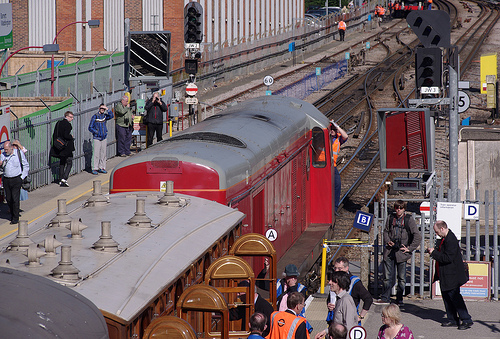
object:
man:
[88, 103, 114, 175]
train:
[0, 95, 334, 339]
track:
[311, 0, 500, 265]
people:
[0, 140, 30, 225]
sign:
[440, 90, 470, 113]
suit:
[51, 118, 76, 182]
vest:
[264, 309, 308, 339]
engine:
[109, 95, 332, 278]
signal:
[414, 47, 443, 173]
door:
[309, 115, 335, 227]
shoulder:
[92, 112, 101, 119]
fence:
[0, 84, 158, 203]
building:
[5, 0, 304, 77]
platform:
[0, 18, 410, 259]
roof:
[109, 95, 330, 192]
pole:
[448, 65, 459, 203]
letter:
[453, 96, 466, 106]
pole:
[49, 54, 56, 97]